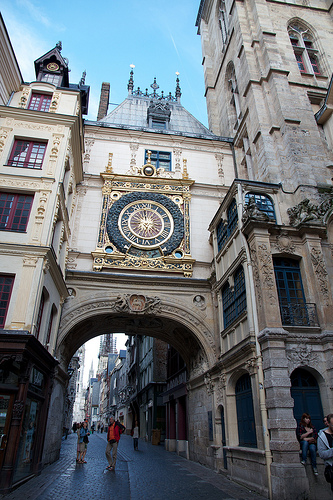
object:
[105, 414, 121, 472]
man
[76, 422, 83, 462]
woman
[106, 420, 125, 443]
shirt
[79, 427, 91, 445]
shirt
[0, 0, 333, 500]
building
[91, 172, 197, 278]
clock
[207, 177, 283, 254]
balcony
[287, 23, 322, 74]
window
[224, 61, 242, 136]
window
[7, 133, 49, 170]
window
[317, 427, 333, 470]
shirt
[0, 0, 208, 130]
cloud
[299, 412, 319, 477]
woman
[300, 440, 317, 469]
jeans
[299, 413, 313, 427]
brown hair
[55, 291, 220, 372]
arch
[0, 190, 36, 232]
window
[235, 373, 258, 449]
window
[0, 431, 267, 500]
road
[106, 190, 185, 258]
gold face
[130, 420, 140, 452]
person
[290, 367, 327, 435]
window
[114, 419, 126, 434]
backpack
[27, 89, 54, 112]
window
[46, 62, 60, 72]
clock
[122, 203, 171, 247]
roman numerals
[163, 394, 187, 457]
doors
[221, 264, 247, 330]
window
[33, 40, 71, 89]
tower